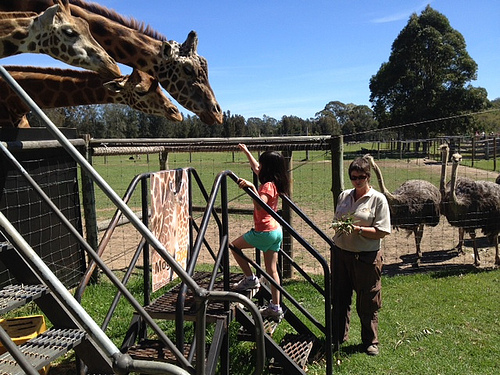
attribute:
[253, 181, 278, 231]
shirt — orange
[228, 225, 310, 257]
shorts — green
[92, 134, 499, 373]
grassy terrain — green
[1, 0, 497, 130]
sky — blue, clear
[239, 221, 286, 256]
shorts — green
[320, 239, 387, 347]
pants — brown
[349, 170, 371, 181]
sunglasses — dark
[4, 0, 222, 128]
giraffe — tall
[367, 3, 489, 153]
tree — large, green